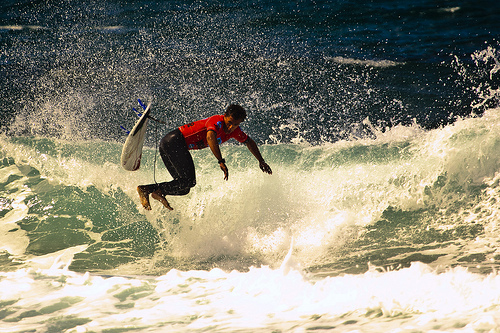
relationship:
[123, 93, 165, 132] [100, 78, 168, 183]
fin on board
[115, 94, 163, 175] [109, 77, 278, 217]
surfboard away from surfer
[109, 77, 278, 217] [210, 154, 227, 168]
surfer wearing watch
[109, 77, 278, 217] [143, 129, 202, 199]
surfer wears wetsuit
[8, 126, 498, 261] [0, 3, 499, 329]
wave of water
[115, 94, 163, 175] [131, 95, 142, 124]
surfboard with handles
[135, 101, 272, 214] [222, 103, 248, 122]
man with hair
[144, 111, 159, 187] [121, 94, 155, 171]
cord holding board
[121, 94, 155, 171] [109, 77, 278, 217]
board to surfer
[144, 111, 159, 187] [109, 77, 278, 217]
cord attached to surfer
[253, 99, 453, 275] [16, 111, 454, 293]
foam in wave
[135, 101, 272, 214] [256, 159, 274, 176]
man has left hand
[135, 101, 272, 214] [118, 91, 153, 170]
man falling off of surfboard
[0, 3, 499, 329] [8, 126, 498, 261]
water has wave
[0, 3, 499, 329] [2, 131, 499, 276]
water behind wave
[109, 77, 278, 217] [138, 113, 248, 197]
surfer wearing water suit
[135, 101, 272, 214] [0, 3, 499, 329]
man falling into water